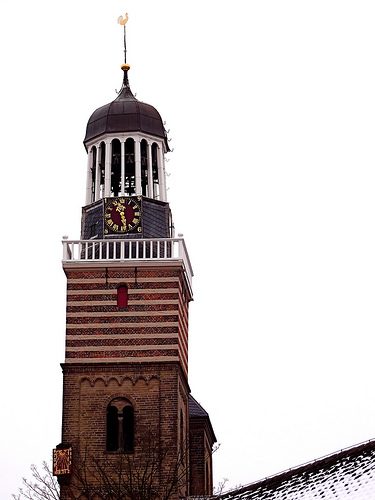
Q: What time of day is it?
A: Daytime.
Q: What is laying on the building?
A: Snow.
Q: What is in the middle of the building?
A: Clock.